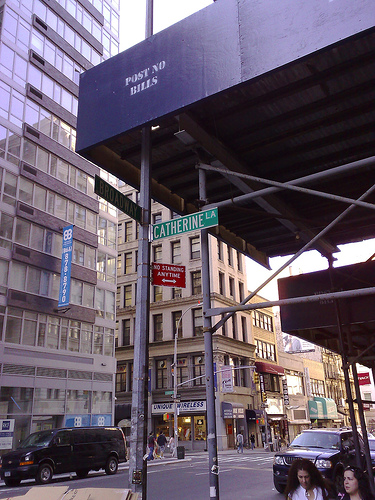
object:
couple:
[284, 457, 374, 500]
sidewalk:
[279, 453, 374, 499]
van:
[2, 425, 129, 482]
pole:
[127, 127, 153, 500]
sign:
[151, 262, 187, 290]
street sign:
[151, 206, 219, 241]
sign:
[57, 225, 75, 308]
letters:
[125, 76, 131, 86]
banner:
[75, 0, 242, 157]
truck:
[273, 427, 374, 497]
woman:
[285, 459, 329, 499]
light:
[172, 302, 204, 457]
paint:
[217, 452, 275, 470]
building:
[0, 0, 123, 483]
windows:
[92, 324, 105, 357]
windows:
[152, 312, 164, 341]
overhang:
[217, 333, 257, 359]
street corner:
[144, 397, 210, 499]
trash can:
[176, 445, 185, 459]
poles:
[197, 161, 221, 499]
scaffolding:
[199, 160, 374, 207]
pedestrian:
[236, 430, 244, 454]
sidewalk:
[116, 447, 191, 471]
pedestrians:
[156, 430, 169, 460]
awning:
[254, 361, 285, 377]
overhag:
[74, 0, 374, 272]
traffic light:
[253, 372, 260, 384]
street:
[0, 451, 291, 499]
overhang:
[307, 396, 338, 419]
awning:
[245, 408, 265, 425]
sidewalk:
[158, 438, 276, 457]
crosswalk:
[191, 452, 275, 465]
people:
[146, 431, 158, 462]